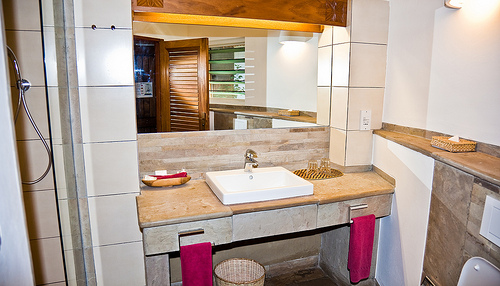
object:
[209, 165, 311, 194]
bathroom sink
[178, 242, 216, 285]
towel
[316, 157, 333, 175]
cup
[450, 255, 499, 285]
toilet seat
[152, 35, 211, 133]
door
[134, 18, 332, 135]
bathroom mirror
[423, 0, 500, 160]
wall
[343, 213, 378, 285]
towel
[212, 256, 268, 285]
basket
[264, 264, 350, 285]
ground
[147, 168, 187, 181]
washcloth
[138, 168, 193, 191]
soap cotainer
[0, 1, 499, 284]
bathroom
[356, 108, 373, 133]
light switch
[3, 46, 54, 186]
shower cord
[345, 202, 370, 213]
towel holder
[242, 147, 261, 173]
faucet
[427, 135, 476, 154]
box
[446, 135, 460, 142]
tissues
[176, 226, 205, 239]
handle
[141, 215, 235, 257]
drawer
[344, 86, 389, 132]
tiles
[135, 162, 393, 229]
countertop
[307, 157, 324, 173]
glass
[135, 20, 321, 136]
reflections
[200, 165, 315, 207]
basin